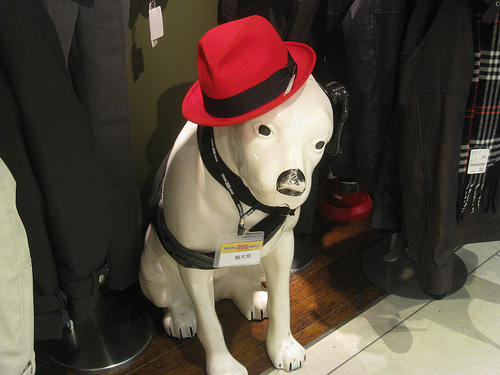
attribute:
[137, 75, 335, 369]
dog — a doll, a color, white, existing, not a berg, ceramic, a sculpture, sculpture, standing, fake, figurine, mannequin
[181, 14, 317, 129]
hat — cap, a color, red, not berg style, very classy looking, black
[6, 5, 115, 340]
coat — hanging, a color, black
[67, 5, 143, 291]
trouser — hanging, a pair, gray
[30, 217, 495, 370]
ground — wooden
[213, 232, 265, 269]
tag — hanging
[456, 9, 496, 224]
scarf — white, black, red, brand new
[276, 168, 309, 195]
nose — a color, black, worn out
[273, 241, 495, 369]
tile — ceramic, white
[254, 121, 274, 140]
eye — black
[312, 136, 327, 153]
eye — black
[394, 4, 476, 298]
jacket — dark, a color, black, hanging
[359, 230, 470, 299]
stand — for hanging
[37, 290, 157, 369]
stand — for hanging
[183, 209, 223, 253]
shadow — a portion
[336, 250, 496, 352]
shadow — a portion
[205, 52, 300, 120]
ribbon — a color, black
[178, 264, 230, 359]
leg — short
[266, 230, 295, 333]
leg — short